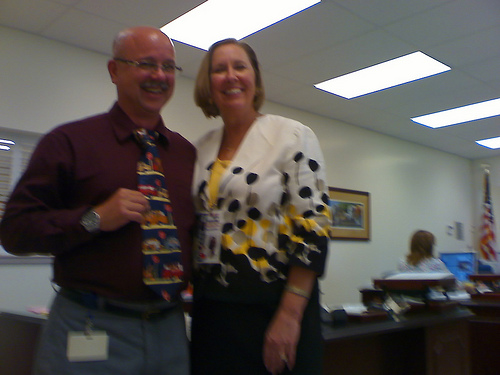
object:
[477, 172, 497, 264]
flag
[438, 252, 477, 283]
monitor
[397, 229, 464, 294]
lady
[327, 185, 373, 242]
frame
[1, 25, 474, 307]
wall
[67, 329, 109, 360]
id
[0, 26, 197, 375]
man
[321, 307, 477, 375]
desk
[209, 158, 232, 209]
shirt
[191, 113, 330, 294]
jacket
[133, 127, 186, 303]
tie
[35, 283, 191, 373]
pants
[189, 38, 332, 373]
woman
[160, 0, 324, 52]
lights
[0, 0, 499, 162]
ceiling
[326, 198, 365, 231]
picture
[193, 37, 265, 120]
hair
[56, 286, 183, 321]
belt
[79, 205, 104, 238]
watch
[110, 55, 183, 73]
glasses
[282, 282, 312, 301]
bracelet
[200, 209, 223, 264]
id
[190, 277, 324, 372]
pants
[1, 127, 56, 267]
window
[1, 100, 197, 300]
shirt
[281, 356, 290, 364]
ring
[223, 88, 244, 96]
teeth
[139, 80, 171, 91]
mustache